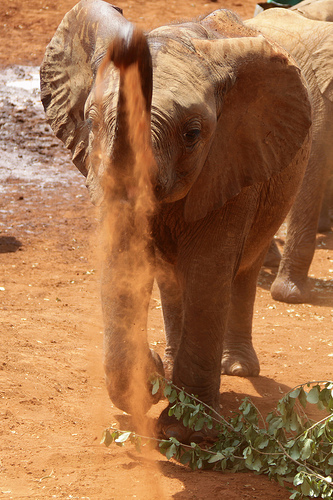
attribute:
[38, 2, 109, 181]
ear — big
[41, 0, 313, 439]
elephant — african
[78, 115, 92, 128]
eyelashes — long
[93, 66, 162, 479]
dirt cloud — dry 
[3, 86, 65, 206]
dirt — wet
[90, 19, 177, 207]
trunk — long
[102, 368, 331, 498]
branches — some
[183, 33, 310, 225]
ear — big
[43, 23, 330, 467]
elephant — big